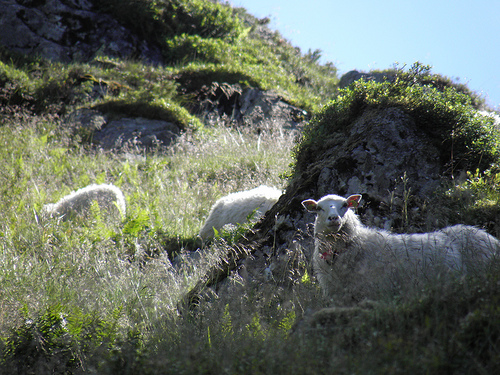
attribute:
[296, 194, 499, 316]
lamb — laying down, white, large, looking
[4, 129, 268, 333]
grass — long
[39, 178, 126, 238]
lamb — white, eating, grazing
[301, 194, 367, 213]
ears — pointy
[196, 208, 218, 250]
neck — down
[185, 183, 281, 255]
lamb — eating, grazing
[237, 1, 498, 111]
sky — blue, clear